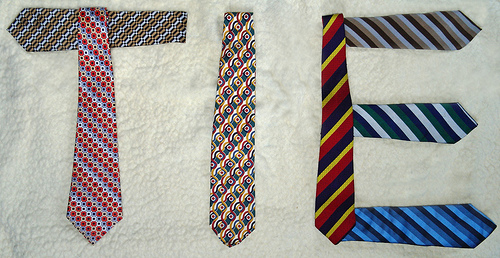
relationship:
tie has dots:
[68, 9, 125, 241] [82, 86, 104, 136]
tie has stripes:
[345, 194, 493, 252] [397, 199, 455, 244]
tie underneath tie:
[9, 8, 188, 53] [68, 9, 125, 241]